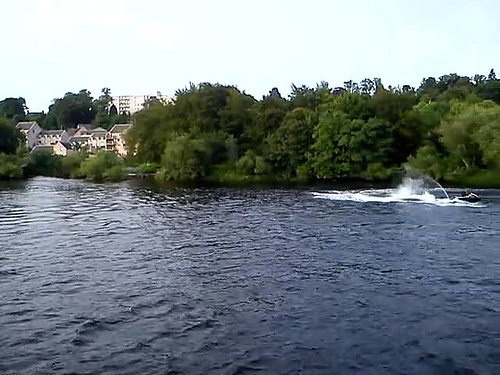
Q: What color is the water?
A: Blue.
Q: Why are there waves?
A: Motions.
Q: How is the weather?
A: Fair.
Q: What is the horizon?
A: Trees.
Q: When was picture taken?
A: Daytime.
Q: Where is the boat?
A: Water.